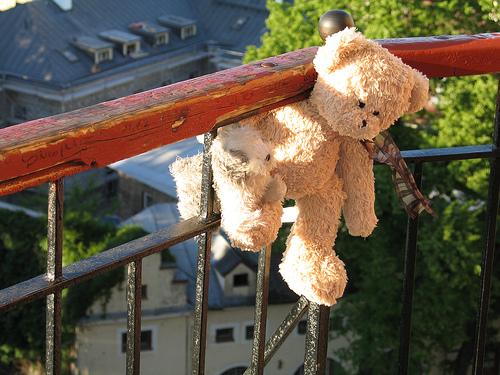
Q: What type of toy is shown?
A: Stuffed bear.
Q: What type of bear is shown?
A: Teddy bear.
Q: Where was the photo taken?
A: Balcony.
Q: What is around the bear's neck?
A: Scarf.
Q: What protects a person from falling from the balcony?
A: Railing.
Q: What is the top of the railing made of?
A: Wood.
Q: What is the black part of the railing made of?
A: Metal.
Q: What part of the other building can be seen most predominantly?
A: Roofs.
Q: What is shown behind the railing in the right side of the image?
A: Tree.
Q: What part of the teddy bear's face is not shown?
A: Mouth.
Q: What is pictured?
A: Stuffed animal.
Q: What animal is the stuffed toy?
A: Bear.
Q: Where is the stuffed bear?
A: In railing.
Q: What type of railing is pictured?
A: Iron.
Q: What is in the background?
A: Buildings.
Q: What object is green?
A: Tree.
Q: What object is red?
A: Railing.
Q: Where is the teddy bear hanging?
A: On a balcony.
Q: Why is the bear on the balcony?
A: It's stuck between railings.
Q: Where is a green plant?
A: Behind the teddy bear.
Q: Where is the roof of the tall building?
A: On the top left side.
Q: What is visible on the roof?
A: Windows.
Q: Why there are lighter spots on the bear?
A: Because of sunshine.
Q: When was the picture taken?
A: During the daytime.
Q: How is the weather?
A: Sunny.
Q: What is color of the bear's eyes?
A: Black.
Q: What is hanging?
A: A bear.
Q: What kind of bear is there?
A: Teddy bear.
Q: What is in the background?
A: Trees.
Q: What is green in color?
A: The tree.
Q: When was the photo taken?
A: During the daytime.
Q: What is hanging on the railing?
A: A teddy bear.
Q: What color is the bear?
A: Brown.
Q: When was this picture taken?
A: Daytime.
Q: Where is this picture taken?
A: A balcony.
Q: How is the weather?
A: Sunny.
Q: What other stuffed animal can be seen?
A: A dog.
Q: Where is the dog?
A: The railing.